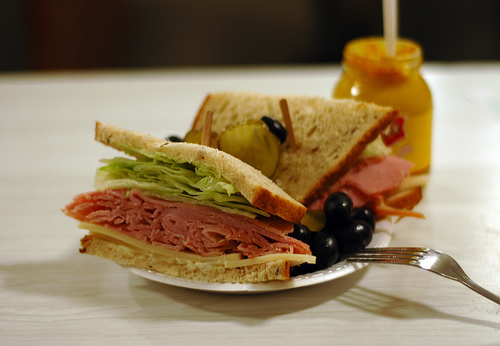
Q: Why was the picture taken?
A: To show healthy choices.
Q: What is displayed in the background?
A: Mustard.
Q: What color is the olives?
A: Black.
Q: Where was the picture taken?
A: At a picnic.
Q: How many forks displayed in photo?
A: One.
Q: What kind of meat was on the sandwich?
A: Ham.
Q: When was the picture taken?
A: Lunch time.